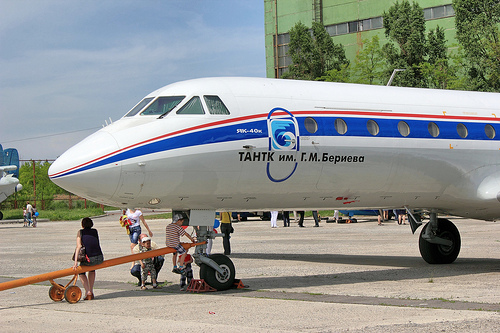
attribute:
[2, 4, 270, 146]
clouds — white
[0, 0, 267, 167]
sky — blue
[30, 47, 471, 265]
plane — blue and white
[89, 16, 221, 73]
clouds — white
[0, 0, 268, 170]
clouds — white